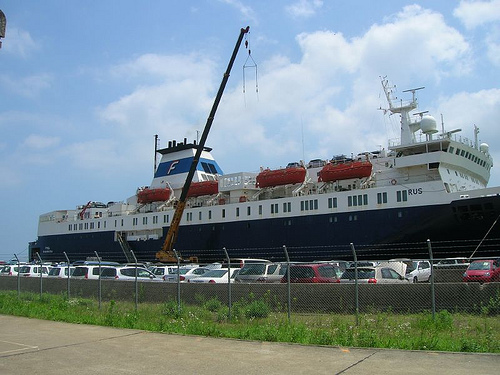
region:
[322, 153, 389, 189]
red life rafts on side of ship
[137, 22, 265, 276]
large crane on the side of the ship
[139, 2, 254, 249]
orange and black crane on side of ship.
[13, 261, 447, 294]
parked cars in a parking lot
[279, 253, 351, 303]
red car parked in the lot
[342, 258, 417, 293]
gold car with its hood up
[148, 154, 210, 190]
large 'F' on the ship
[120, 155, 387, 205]
4 life rafts on the ship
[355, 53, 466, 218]
radio equipment on the ship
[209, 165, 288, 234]
balcony on the ship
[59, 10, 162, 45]
The sky is blue.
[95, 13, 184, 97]
The sky has clouds in it.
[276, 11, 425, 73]
The clouds are white and blue.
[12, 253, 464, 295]
A row of cars.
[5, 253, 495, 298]
The cars are parked.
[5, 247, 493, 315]
A fence is behind the cars.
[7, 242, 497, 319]
The fence is made of wire.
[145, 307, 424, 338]
The grass is green.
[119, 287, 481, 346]
The grass is tall.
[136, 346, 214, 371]
The ground is gray.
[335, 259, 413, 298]
gold car with hood up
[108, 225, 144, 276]
stairs leading to the ship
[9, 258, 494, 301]
cars in a parking lot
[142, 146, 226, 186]
Big 'F' On the side of the ship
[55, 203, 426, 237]
rows of windows on the ship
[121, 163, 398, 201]
life rafts on the side of the ship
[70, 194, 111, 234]
small red crane on the ship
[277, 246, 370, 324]
red car parked near the ship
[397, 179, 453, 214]
identification of the ship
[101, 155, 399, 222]
The life boats are red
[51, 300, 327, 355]
The grass is green and tall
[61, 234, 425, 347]
The fence is metal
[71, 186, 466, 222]
The boat has many windows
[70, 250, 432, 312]
The cars are parked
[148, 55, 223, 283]
The crane is made of metal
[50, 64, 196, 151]
The sky is blue and cloudy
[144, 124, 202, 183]
The ship has a F on it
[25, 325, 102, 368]
The side walk is gray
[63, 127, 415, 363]
The boat is blue and white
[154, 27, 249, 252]
a crane next to the boat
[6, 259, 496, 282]
the parking lot full of cars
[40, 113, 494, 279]
the boat next to the parking lot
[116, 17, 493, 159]
the white clouds in the air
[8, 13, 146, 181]
the blue patch of the sky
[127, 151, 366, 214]
a line of rowboats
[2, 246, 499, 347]
a fence next to the parking lot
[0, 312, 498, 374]
the sidewalk next to the parking lot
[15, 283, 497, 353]
the grass on the ground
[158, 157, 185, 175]
a letter on the stack